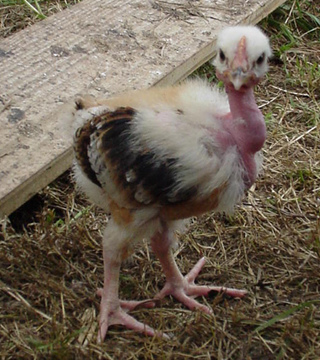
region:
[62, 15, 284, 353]
this is a hen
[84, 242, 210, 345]
these are the two legs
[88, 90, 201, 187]
the feathers are white in color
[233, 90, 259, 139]
this is the neck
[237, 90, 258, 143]
the neck is long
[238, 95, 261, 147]
the neck is red in color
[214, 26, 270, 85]
this is the head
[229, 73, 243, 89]
the beak is short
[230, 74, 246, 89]
the beak is sharp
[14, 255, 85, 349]
the dry grass are on the ground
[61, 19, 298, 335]
young turkey standing on hay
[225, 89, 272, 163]
pink neck of bird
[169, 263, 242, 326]
toes on bird foot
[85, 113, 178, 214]
wing on bird body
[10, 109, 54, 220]
dirty board on ground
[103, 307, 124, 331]
webbing between bird toes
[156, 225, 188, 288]
pink leg on turkey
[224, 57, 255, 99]
beak on bird's face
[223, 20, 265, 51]
white fluff on head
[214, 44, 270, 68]
two eyes on head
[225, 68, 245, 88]
The chicken's beak.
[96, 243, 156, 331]
The left leg of the chicken.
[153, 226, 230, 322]
The right leg of the chicken.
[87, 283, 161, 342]
The left foot of the chicken.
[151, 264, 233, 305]
The right foot of the chicken.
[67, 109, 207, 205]
The brown and white feathers of the chicken.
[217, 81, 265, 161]
The neck of the chicken.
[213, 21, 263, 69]
The white fur on the chicken's head.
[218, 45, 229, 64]
The left eye of the chicken.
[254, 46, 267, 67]
The right eye of the chicken.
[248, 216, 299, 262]
brown grass on ground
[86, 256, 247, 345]
two pink bird feet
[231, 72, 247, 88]
white beak of bird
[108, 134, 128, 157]
black feathers on bird wing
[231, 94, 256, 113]
pink featherless bird neck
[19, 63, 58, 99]
brown wooden board laying on ground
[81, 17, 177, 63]
dirt on top of wooden board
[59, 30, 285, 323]
baby bird standing in grass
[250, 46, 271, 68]
black baby bird eye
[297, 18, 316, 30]
green blade of grass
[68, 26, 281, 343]
a small baby ostrich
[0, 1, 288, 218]
a wooden board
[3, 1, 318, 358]
grass under a baby ostrich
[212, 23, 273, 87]
a white fluffy baby ostrich head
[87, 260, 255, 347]
bare skinned baby ostrich feet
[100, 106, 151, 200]
dark brown feathers on a baby ostrich's side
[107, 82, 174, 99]
light brown fluffy feathers on a baby ostrich back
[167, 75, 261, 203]
a fluffy white ring of feathers under a baby ostrich neck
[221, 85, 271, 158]
a pink bare skin baby ostrich neck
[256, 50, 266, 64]
a dark eye